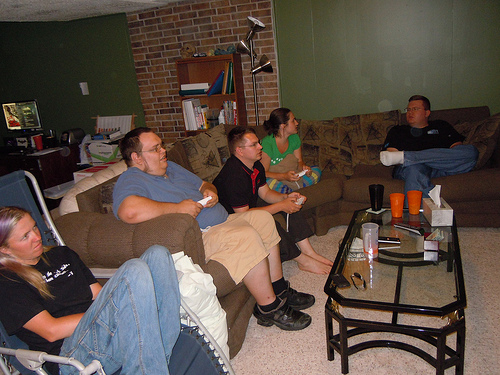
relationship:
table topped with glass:
[319, 199, 475, 374] [404, 278, 436, 300]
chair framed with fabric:
[0, 167, 236, 373] [4, 168, 234, 373]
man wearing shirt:
[107, 130, 316, 329] [110, 158, 229, 229]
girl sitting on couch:
[260, 108, 325, 193] [169, 101, 499, 228]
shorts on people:
[206, 206, 288, 285] [2, 95, 475, 375]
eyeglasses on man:
[130, 142, 165, 152] [107, 130, 316, 329]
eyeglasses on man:
[130, 143, 162, 153] [107, 130, 316, 329]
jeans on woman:
[92, 255, 179, 366] [0, 196, 202, 368]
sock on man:
[376, 145, 406, 170] [379, 90, 479, 191]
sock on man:
[252, 292, 284, 313] [206, 124, 306, 217]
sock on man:
[271, 274, 291, 294] [116, 119, 227, 229]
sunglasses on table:
[348, 268, 365, 290] [319, 199, 475, 374]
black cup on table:
[367, 182, 387, 212] [319, 199, 475, 374]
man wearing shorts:
[107, 130, 316, 329] [201, 208, 282, 284]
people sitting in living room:
[2, 95, 475, 375] [1, 0, 498, 374]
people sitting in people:
[2, 95, 475, 375] [2, 95, 475, 375]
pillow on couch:
[301, 126, 353, 173] [77, 105, 497, 354]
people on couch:
[2, 90, 487, 369] [185, 91, 498, 244]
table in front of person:
[319, 199, 475, 374] [378, 95, 477, 195]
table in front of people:
[319, 199, 475, 374] [2, 95, 475, 375]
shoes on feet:
[251, 279, 315, 331] [255, 272, 324, 343]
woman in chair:
[1, 204, 185, 374] [0, 167, 236, 373]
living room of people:
[1, 0, 499, 375] [2, 90, 487, 369]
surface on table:
[328, 201, 471, 313] [319, 199, 475, 374]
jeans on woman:
[49, 241, 179, 374] [1, 204, 185, 374]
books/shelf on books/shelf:
[175, 54, 241, 129] [175, 54, 241, 129]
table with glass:
[319, 199, 475, 374] [355, 212, 455, 323]